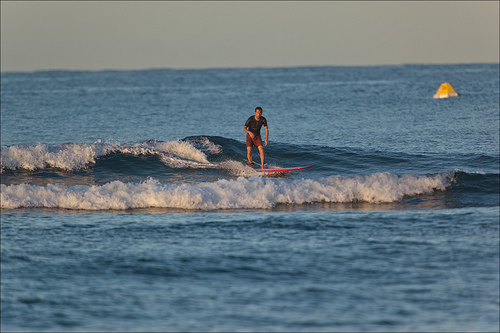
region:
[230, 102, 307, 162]
A person walking in water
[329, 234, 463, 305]
A blue still water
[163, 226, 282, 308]
A blue still water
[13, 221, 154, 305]
A blue still water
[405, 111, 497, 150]
A blue still water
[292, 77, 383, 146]
A blue still water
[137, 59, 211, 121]
A blue still water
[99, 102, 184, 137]
A blue still water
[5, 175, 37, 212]
Small ripples in the water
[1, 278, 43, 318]
Small ripples in the water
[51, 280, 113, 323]
Small ripples in the water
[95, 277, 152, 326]
Small ripples in the water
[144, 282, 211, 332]
Small ripples in the water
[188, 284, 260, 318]
Small ripples in the water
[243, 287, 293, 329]
Small ripples in the water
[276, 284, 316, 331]
Small ripples in the water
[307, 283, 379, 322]
Small ripples in the water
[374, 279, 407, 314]
Small ripples in the water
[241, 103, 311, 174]
surfer riding a wave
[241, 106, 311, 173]
surfer wearing red trunks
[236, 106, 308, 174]
surfer riding a red surfboard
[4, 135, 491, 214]
waves crashing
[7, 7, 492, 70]
a gray, dusky sky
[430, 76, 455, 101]
floating yellow buoy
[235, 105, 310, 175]
surfer prepares for next wave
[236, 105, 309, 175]
surfer wearing dark top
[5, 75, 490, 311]
deep blue ocean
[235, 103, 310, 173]
surfer bends at the knees to brace himself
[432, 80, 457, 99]
a yellow buoy in the distance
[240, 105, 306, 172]
a surfer catching a wave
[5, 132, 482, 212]
a small wave in the ocean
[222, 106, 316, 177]
a surfer with a black shirt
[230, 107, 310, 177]
a surfer with red shorts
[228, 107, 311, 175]
a surfer with a red surfboard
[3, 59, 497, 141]
an empty horizon on the ocean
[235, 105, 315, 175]
a surfer practicing his sport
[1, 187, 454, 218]
a slight reflection of a wave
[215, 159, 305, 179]
a small wake from a surfboard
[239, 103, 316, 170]
man on a swimming boat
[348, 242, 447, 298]
water is blue in color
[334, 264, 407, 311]
part of the blue water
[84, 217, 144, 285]
part oof the blue water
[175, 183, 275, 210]
the waves are white in color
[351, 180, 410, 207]
part of the white water waves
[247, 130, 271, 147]
the shorts are brown in color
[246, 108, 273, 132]
the shirt is black in color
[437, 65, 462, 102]
a yellow boat in middle of ocean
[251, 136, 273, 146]
short is grey in color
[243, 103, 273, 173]
surfer on the red surf board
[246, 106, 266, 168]
a man on a surfboard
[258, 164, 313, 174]
a white surfboard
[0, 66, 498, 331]
a large body of water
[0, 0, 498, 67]
a cloudy gray sky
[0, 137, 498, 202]
a wave in the ocean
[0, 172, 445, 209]
the frothy head of a wave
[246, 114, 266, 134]
a black shirt on a man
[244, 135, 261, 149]
brown shorts on a man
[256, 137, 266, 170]
a man's leg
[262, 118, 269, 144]
a man's arm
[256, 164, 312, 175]
Red surfboard on the sea.